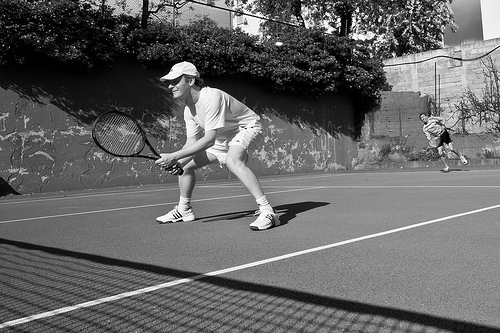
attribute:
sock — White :
[254, 193, 274, 215]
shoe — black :
[248, 202, 283, 233]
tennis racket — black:
[91, 108, 184, 177]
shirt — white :
[182, 85, 259, 146]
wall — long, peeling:
[3, 74, 419, 198]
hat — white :
[166, 59, 193, 81]